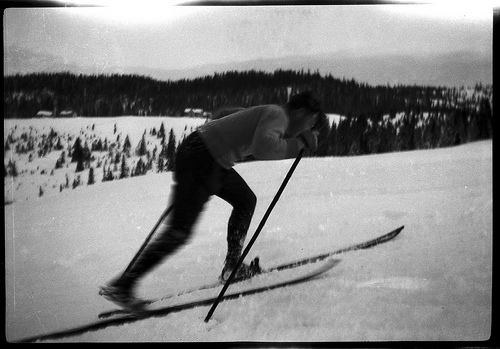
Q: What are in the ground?
A: Snow.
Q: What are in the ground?
A: Shadow.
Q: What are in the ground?
A: Pole.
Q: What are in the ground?
A: Sticks.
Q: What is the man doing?
A: Holding.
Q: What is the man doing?
A: Holding.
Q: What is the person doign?
A: Skiing.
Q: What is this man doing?
A: Skiing.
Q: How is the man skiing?
A: Uphill.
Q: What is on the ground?
A: Snow.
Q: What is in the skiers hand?
A: Ski pole.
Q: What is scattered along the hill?
A: Trees.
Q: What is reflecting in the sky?
A: Light.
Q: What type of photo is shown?
A: Black and white.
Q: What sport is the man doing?
A: Skiing.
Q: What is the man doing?
A: Skiing.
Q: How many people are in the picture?
A: One.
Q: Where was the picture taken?
A: A ski slope.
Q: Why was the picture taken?
A: To capture the man.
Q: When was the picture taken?
A: During the day.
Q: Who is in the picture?
A: A man.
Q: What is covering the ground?
A: Snow.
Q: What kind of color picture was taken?
A: Black and white.